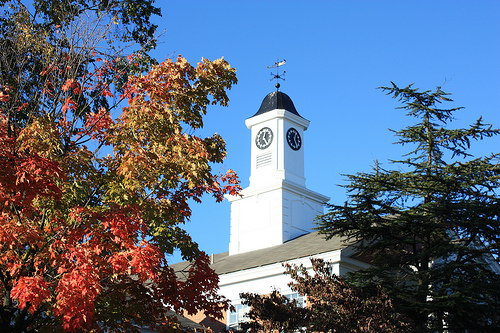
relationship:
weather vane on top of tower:
[266, 56, 288, 91] [221, 87, 329, 259]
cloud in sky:
[154, 48, 214, 83] [163, 10, 208, 48]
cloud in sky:
[0, 0, 500, 267] [0, 1, 499, 279]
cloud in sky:
[0, 0, 500, 267] [332, 38, 412, 60]